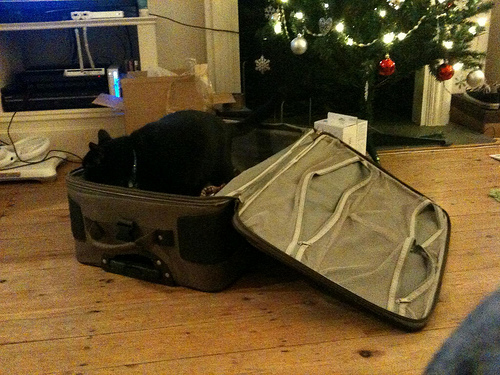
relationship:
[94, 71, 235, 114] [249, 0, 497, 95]
box by tree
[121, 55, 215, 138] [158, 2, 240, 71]
open box near wall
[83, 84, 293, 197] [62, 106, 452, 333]
cat inside luggage case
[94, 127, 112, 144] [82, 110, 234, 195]
ear on cat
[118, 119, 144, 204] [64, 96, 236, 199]
collar on cat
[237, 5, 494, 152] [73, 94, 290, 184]
christmas tree behind cat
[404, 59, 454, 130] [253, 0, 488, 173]
package under tree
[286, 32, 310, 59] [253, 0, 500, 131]
ornament on christmas tree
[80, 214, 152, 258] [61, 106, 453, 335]
handle on luggage case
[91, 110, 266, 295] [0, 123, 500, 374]
luggage case on floor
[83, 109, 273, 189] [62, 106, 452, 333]
cat on luggage case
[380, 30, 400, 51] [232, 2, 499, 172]
light on tree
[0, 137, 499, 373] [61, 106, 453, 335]
floor under luggage case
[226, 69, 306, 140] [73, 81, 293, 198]
tail on cat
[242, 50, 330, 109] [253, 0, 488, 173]
section of fireplace behind tree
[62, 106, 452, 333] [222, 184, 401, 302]
luggage case on its side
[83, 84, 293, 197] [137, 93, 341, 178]
cat wearing a collar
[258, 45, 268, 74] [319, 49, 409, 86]
star shape tree ornament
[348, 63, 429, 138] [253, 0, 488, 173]
base on tree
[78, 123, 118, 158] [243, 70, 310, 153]
ears of cat